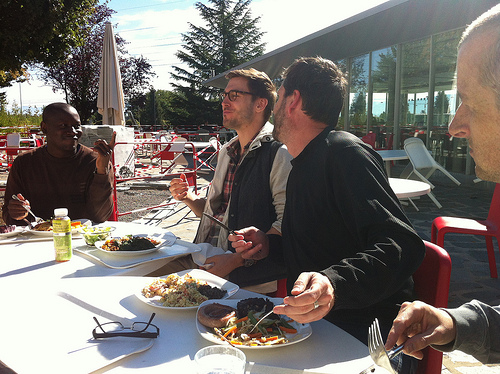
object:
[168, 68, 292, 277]
man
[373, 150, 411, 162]
table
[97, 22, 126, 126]
umbrella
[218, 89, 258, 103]
eyeglasses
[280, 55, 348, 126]
hair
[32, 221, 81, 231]
food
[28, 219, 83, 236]
white plate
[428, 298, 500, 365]
shirt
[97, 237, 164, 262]
ceramic plate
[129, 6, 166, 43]
cloud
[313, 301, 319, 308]
ring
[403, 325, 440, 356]
finger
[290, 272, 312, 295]
finger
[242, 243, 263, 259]
finger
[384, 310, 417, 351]
finger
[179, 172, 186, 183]
finger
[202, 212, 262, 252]
knife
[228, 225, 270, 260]
right hand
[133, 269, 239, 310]
plate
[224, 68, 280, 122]
hair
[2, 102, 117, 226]
man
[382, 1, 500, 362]
man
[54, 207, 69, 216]
cap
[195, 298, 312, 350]
plate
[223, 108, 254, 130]
beard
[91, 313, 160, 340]
eyeglasses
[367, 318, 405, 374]
fork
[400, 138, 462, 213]
chair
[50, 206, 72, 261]
beverage bottle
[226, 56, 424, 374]
man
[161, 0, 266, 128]
tree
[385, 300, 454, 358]
hand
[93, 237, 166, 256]
plates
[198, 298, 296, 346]
food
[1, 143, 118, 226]
brown shirt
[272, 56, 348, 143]
head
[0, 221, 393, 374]
table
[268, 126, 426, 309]
shirt